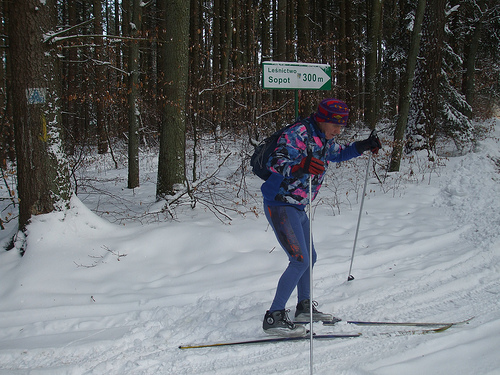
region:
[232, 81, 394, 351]
Woman skiing in the snow.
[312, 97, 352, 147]
Hat on the woman.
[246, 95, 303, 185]
Backpack on the woman's back.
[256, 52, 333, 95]
Sign behind the woman.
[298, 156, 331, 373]
Ski pole in woman's hand.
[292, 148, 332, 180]
Red and black glove on the hand.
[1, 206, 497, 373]
Tracks in the snow.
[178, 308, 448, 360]
Snow skis on the woman.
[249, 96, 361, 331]
Blue ski pants on the woman.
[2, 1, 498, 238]
Trees in the background.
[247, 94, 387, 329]
the man wearing skis on the hill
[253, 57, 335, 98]
a sign pointing up the hill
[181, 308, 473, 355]
the skis the man is wearing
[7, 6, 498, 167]
assorted trees along the hill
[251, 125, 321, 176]
the backpack the man is wearing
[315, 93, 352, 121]
the hat on the man's head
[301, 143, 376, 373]
the ski poles the man is holding onto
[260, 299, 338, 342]
the shoes on the mans feet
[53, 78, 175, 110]
dead leaves on the trees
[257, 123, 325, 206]
the sweater the man is wearing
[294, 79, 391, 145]
the head of a person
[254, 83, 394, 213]
a person with a jacket on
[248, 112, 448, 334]
a person wearing pants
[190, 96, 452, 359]
a person with skis on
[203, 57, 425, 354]
a person in the snow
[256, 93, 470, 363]
a person holding ski sticks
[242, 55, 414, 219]
a person with a bookbag on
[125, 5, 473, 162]
trees with no leaves on them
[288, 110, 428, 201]
a person wearing gloves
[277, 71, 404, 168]
a person with a hat on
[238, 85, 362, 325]
this is an old lady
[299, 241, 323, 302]
this is a stick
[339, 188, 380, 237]
the stick is thin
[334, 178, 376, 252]
the stick is long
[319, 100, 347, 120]
this is a marvin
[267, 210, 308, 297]
the stockings are blue in color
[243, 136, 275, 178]
this is a bag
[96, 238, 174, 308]
the place is full of snow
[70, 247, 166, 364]
the snow is white in color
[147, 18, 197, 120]
this is a tree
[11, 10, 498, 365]
picture taken outdoors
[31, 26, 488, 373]
picture taken during the day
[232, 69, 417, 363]
a woman is sking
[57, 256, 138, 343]
the ground is covered in snow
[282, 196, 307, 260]
the woman wears blue ski pants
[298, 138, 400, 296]
the woman holds ski poles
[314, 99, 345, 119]
the woman wears a hat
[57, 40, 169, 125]
the trees are without leaves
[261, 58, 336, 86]
a sign with an arrow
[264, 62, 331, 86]
the sign is white and green